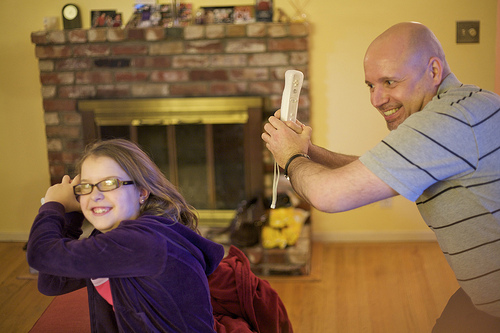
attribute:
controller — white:
[269, 68, 305, 211]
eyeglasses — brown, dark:
[71, 177, 143, 199]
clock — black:
[62, 1, 83, 33]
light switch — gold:
[455, 19, 481, 45]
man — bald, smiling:
[261, 21, 500, 332]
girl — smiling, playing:
[28, 138, 239, 332]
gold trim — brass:
[78, 96, 265, 233]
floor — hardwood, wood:
[0, 237, 499, 331]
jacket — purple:
[21, 198, 224, 331]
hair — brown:
[74, 138, 204, 239]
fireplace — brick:
[28, 23, 311, 272]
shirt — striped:
[358, 72, 499, 323]